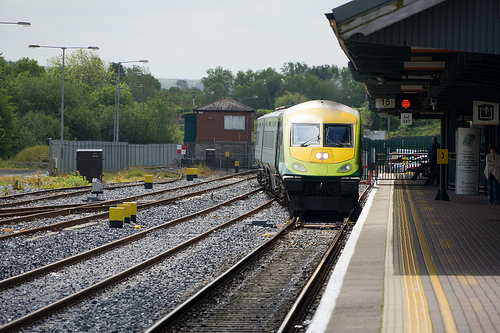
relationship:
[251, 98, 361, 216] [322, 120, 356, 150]
train has window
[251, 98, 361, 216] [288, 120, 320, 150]
train has window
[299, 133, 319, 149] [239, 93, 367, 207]
wiper on train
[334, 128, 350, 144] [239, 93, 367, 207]
wiper on train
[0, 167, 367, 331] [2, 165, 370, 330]
rail on ground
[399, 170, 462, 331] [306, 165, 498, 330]
line on platform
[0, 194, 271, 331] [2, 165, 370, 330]
rail on ground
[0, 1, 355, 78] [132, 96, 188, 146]
sky over tree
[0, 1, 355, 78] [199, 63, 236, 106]
sky over tree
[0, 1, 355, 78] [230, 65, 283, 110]
sky over tree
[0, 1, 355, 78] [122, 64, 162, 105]
sky over tree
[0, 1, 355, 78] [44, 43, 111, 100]
sky over tree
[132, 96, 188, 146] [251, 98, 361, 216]
tree behind train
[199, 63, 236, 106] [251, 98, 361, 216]
tree behind train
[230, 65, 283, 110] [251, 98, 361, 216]
tree behind train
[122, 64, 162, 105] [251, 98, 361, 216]
tree behind train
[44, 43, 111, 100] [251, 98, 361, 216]
tree behind train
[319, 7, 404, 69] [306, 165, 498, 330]
roof over platform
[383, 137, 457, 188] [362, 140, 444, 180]
cars behind fence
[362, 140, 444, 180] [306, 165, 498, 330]
fence at end of platform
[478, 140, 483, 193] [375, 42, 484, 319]
woman in shade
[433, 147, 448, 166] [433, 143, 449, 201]
sign on post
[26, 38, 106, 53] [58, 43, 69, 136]
streetlights on pole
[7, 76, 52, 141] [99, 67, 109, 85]
tree with leaves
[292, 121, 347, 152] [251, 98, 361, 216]
windshield on train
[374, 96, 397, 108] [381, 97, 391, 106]
sign with black number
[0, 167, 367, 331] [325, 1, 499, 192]
rail at station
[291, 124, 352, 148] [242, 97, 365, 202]
windshield on train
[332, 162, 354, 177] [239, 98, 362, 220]
headlight on train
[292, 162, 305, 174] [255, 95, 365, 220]
headlight on a train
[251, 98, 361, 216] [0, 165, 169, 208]
train on track